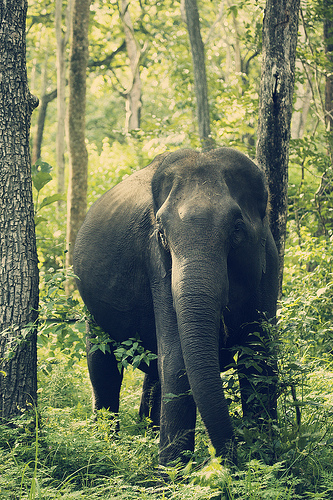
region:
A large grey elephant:
[68, 142, 307, 469]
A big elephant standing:
[70, 140, 307, 445]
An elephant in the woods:
[61, 138, 332, 475]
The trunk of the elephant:
[180, 262, 247, 463]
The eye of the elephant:
[229, 218, 246, 238]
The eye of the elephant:
[151, 227, 168, 238]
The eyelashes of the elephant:
[146, 226, 157, 237]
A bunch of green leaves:
[22, 289, 155, 376]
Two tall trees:
[51, 69, 91, 212]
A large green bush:
[5, 442, 174, 497]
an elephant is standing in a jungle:
[13, 5, 332, 493]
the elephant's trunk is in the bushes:
[192, 385, 248, 491]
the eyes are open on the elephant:
[150, 213, 249, 251]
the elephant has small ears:
[142, 151, 274, 297]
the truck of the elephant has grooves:
[171, 248, 239, 475]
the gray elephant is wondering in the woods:
[3, 1, 326, 489]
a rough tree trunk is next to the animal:
[3, 85, 132, 402]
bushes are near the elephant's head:
[204, 205, 331, 450]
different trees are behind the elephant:
[29, 2, 330, 294]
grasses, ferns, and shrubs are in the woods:
[5, 264, 329, 489]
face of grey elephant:
[145, 146, 272, 307]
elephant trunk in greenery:
[191, 407, 289, 480]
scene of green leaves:
[46, 423, 132, 483]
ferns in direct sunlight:
[188, 464, 228, 499]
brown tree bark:
[2, 208, 31, 328]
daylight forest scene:
[39, 24, 168, 96]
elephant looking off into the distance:
[152, 197, 263, 304]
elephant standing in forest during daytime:
[74, 92, 290, 304]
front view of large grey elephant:
[101, 152, 289, 336]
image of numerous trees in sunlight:
[42, 15, 219, 97]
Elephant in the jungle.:
[54, 153, 311, 483]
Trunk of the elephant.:
[168, 247, 273, 482]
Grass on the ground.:
[48, 423, 172, 498]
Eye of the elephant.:
[231, 217, 243, 241]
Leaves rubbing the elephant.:
[79, 306, 160, 385]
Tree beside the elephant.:
[0, 141, 49, 441]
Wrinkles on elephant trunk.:
[182, 259, 215, 332]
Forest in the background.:
[44, 65, 325, 133]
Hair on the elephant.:
[245, 155, 279, 213]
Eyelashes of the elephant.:
[149, 225, 164, 233]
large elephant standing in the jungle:
[71, 147, 286, 499]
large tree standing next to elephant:
[0, 0, 46, 467]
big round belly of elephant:
[72, 192, 151, 345]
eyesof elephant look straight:
[158, 218, 244, 250]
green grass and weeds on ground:
[0, 418, 330, 499]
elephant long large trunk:
[170, 249, 245, 464]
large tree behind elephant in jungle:
[256, 0, 303, 327]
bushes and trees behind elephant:
[278, 173, 330, 499]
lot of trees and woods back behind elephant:
[25, 2, 262, 153]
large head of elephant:
[151, 145, 266, 269]